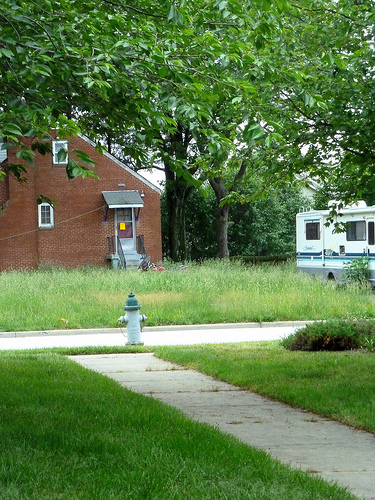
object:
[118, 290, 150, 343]
fire hydrant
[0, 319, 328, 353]
road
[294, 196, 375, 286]
rv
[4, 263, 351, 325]
grass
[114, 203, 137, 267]
door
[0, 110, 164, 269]
building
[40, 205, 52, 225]
window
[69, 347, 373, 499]
sidewalk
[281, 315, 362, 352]
bush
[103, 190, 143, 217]
cover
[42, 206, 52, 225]
windows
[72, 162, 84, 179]
leaves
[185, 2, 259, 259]
trees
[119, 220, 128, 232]
note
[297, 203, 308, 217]
ladder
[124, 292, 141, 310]
top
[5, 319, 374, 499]
yard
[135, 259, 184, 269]
motorcycle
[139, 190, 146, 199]
light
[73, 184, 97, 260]
wall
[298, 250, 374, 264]
lines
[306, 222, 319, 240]
window